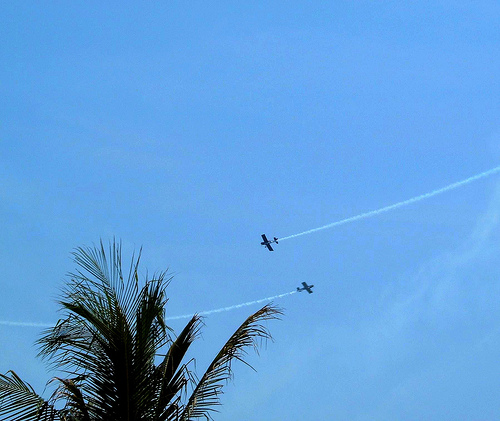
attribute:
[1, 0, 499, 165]
sky — blue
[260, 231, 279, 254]
airplane — flying, flying low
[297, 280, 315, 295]
plane — flying low, flying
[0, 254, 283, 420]
tree — coconut palm, green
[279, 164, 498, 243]
line — another, long, smoke, behind, white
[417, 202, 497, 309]
cloud — white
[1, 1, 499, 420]
wind — blowing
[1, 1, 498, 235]
sky — blue